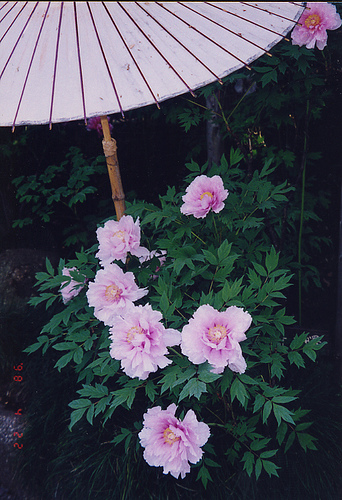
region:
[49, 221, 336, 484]
A bush has flowers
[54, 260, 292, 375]
The flowers are pink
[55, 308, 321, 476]
The pink flowers are in bloom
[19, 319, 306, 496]
The leaves are green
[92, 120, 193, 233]
A bamboo stick is above the flowers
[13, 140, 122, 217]
The leaves in the back are green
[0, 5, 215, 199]
An umbrella is above the bamboo stick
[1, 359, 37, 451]
The umbrella is pink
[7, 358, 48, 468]
The picture was taken in 1998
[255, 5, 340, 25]
A flower is behind the umbrella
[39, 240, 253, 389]
nice set of flowers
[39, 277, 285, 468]
beautiful set of flowers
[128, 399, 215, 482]
a budding pink flower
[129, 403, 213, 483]
nice budding pink flower on tree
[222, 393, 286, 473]
some green leaves on tree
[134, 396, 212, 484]
a lovely pink flower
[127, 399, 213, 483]
healthy looking pink flower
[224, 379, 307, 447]
some healthy green leaves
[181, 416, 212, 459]
some petals on a flower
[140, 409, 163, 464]
petals on a pink flower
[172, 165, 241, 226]
Pink and yellow flower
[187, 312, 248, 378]
Pink and yellow flower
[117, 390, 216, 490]
Pink and yellow flower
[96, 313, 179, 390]
Pink and yellow flower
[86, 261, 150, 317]
Pink and yellow flower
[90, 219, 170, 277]
Pink and yellow flower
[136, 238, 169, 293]
Pink and yellow flower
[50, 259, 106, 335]
Pink and yelloPink and yellow flowerw flower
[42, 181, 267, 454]
Pink and yellow flowers in a bush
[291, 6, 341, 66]
Pink and yellow flower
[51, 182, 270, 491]
pink flowers on plant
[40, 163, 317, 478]
green leaves of plant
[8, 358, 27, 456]
tiny red flowers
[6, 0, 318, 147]
umbrella shading pink flowers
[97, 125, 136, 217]
wooden handle of umbrella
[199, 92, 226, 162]
tree trunk behind flower bush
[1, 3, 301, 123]
white umbrella over top of flowers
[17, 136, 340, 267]
foliage behind flower bush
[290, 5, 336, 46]
pink flower beside umbrlella brim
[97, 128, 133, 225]
umbrella handle stuck in flower bush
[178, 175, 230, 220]
a pink flower with a yellow center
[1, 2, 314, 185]
an umbrella over pink flowers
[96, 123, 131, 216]
the bamboo stick holding up the umbrella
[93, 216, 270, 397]
a bunch of flowers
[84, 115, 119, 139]
a flower under the umbrella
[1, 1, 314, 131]
line details of the umbrella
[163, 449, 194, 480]
the flower petals have uneven edges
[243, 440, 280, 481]
the leaves are green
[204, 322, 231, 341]
the center is yellow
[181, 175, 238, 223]
a pretty flower under an umbrella